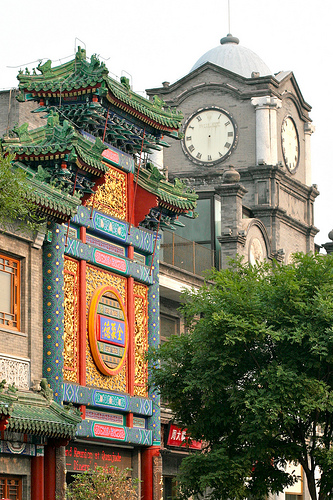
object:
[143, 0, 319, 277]
clock tower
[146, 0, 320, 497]
building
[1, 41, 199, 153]
roof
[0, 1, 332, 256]
sky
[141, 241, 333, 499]
tree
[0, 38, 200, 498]
buildings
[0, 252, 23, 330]
window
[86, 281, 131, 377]
sign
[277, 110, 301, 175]
clock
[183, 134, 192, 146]
roman numerals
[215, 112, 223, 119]
roman numeral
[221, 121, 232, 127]
roman numeral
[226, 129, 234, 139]
roman numeral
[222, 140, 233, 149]
roman numeral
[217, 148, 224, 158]
roman numeral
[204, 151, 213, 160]
roman numeral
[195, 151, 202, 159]
roman numeral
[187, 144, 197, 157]
roman numeral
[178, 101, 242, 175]
clocks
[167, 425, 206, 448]
asian print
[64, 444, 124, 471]
text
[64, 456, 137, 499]
tree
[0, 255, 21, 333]
frame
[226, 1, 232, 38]
pole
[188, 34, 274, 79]
dome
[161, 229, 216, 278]
fence